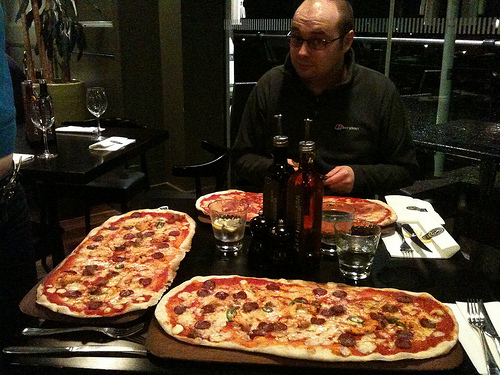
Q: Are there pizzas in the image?
A: Yes, there is a pizza.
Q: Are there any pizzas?
A: Yes, there is a pizza.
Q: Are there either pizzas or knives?
A: Yes, there is a pizza.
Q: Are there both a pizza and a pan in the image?
A: No, there is a pizza but no pans.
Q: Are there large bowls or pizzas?
A: Yes, there is a large pizza.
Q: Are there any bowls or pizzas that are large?
A: Yes, the pizza is large.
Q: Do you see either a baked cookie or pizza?
A: Yes, there is a baked pizza.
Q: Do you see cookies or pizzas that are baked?
A: Yes, the pizza is baked.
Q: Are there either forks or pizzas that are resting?
A: Yes, the pizza is resting.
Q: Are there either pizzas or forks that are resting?
A: Yes, the pizza is resting.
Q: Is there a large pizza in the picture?
A: Yes, there is a large pizza.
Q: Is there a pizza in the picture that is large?
A: Yes, there is a pizza that is large.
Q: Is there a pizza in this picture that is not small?
A: Yes, there is a large pizza.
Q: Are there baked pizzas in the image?
A: Yes, there is a baked pizza.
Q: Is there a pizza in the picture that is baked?
A: Yes, there is a pizza that is baked.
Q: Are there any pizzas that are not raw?
A: Yes, there is a baked pizza.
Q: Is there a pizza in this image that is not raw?
A: Yes, there is a baked pizza.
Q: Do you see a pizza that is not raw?
A: Yes, there is a baked pizza.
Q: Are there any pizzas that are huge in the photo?
A: Yes, there is a huge pizza.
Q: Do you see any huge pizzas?
A: Yes, there is a huge pizza.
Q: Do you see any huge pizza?
A: Yes, there is a huge pizza.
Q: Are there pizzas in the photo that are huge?
A: Yes, there is a pizza that is huge.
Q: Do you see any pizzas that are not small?
A: Yes, there is a huge pizza.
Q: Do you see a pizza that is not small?
A: Yes, there is a huge pizza.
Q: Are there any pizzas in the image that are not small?
A: Yes, there is a huge pizza.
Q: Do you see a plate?
A: No, there are no plates.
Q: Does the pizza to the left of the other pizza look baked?
A: Yes, the pizza is baked.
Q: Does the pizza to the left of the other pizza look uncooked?
A: No, the pizza is baked.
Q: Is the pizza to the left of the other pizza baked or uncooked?
A: The pizza is baked.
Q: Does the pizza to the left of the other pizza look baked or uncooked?
A: The pizza is baked.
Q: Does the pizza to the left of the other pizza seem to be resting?
A: Yes, the pizza is resting.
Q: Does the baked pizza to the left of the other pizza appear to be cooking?
A: No, the pizza is resting.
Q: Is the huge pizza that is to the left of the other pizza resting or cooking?
A: The pizza is resting.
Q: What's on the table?
A: The pizza is on the table.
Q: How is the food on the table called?
A: The food is a pizza.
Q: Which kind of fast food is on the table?
A: The food is a pizza.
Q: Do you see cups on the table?
A: No, there is a pizza on the table.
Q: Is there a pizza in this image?
A: Yes, there is a pizza.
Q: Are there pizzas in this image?
A: Yes, there is a pizza.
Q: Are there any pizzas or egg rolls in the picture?
A: Yes, there is a pizza.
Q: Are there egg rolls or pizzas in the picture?
A: Yes, there is a pizza.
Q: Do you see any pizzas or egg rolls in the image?
A: Yes, there is a pizza.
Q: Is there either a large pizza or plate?
A: Yes, there is a large pizza.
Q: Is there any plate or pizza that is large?
A: Yes, the pizza is large.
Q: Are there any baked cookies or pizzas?
A: Yes, there is a baked pizza.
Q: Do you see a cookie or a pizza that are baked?
A: Yes, the pizza is baked.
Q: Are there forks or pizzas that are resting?
A: Yes, the pizza is resting.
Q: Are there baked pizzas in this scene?
A: Yes, there is a baked pizza.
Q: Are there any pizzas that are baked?
A: Yes, there is a pizza that is baked.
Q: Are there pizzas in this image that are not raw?
A: Yes, there is a baked pizza.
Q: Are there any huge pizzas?
A: Yes, there is a huge pizza.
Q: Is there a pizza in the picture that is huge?
A: Yes, there is a pizza that is huge.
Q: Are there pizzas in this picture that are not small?
A: Yes, there is a huge pizza.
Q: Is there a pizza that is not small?
A: Yes, there is a huge pizza.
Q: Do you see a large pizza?
A: Yes, there is a large pizza.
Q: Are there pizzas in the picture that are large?
A: Yes, there is a pizza that is large.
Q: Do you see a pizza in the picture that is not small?
A: Yes, there is a large pizza.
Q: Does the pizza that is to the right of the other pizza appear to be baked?
A: Yes, the pizza is baked.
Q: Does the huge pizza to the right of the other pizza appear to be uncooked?
A: No, the pizza is baked.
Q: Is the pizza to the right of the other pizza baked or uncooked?
A: The pizza is baked.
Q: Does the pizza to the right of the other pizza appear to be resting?
A: Yes, the pizza is resting.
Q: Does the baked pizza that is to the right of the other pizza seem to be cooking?
A: No, the pizza is resting.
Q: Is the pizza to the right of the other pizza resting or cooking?
A: The pizza is resting.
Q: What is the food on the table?
A: The food is a pizza.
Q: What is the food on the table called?
A: The food is a pizza.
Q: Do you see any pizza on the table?
A: Yes, there is a pizza on the table.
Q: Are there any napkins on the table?
A: No, there is a pizza on the table.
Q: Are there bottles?
A: Yes, there is a bottle.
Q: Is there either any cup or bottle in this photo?
A: Yes, there is a bottle.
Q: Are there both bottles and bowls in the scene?
A: No, there is a bottle but no bowls.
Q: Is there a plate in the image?
A: No, there are no plates.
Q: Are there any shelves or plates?
A: No, there are no plates or shelves.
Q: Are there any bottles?
A: Yes, there is a bottle.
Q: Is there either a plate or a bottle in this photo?
A: Yes, there is a bottle.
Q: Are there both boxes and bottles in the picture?
A: No, there is a bottle but no boxes.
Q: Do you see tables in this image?
A: Yes, there is a table.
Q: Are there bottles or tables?
A: Yes, there is a table.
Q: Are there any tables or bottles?
A: Yes, there is a table.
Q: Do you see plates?
A: No, there are no plates.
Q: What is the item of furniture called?
A: The piece of furniture is a table.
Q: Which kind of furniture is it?
A: The piece of furniture is a table.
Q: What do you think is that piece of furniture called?
A: This is a table.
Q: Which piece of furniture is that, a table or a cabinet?
A: This is a table.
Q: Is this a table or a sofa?
A: This is a table.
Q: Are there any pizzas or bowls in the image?
A: Yes, there is a pizza.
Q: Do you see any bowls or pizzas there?
A: Yes, there is a pizza.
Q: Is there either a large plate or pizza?
A: Yes, there is a large pizza.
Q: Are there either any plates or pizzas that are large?
A: Yes, the pizza is large.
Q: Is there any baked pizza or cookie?
A: Yes, there is a baked pizza.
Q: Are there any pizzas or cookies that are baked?
A: Yes, the pizza is baked.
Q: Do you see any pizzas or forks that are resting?
A: Yes, the pizza is resting.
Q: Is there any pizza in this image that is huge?
A: Yes, there is a huge pizza.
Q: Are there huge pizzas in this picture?
A: Yes, there is a huge pizza.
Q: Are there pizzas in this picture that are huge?
A: Yes, there is a pizza that is huge.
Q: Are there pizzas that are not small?
A: Yes, there is a huge pizza.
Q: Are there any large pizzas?
A: Yes, there is a large pizza.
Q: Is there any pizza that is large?
A: Yes, there is a pizza that is large.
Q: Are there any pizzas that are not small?
A: Yes, there is a large pizza.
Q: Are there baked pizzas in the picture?
A: Yes, there is a baked pizza.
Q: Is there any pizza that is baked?
A: Yes, there is a pizza that is baked.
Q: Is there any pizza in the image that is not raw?
A: Yes, there is a baked pizza.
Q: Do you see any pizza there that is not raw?
A: Yes, there is a baked pizza.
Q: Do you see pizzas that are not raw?
A: Yes, there is a baked pizza.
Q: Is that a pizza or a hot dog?
A: That is a pizza.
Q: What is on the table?
A: The pizza is on the table.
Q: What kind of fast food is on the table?
A: The food is a pizza.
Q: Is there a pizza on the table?
A: Yes, there is a pizza on the table.